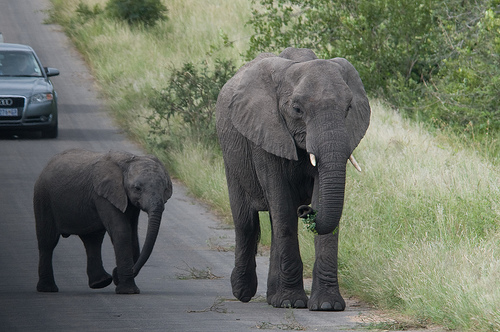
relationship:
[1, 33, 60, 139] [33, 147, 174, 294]
audi car behind elephant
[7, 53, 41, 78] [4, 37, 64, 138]
man drives car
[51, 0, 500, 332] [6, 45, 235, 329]
grass next road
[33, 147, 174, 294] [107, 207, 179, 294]
elephant has trunk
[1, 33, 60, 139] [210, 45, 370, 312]
audi car behind elephant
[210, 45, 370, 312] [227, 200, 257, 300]
elephant has leg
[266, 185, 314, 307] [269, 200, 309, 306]
elephant has leg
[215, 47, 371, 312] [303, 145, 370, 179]
elephant has tusks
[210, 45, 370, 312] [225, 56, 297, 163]
elephant has ear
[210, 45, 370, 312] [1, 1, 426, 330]
elephant on road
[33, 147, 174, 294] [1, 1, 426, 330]
elephant on road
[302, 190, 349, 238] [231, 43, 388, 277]
branch on elephant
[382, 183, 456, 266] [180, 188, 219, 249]
grass on road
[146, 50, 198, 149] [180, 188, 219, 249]
brush on road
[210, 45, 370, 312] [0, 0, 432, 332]
elephant on paved road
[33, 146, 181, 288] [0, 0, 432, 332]
elephant on paved road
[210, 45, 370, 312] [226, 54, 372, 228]
elephant has head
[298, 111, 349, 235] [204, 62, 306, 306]
elephant nose of elephant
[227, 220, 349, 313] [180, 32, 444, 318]
legs of elephant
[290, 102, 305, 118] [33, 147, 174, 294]
eye of an elephant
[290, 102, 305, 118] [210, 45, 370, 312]
eye of an elephant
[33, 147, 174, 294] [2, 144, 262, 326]
elephant on street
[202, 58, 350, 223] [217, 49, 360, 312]
body of elephant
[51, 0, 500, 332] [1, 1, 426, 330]
grass strewn on road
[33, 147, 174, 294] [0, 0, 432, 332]
elephant walks on paved road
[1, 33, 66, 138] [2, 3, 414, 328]
audi car on paved road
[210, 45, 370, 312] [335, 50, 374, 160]
elephant has ear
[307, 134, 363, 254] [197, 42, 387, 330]
elephant nose on elephant